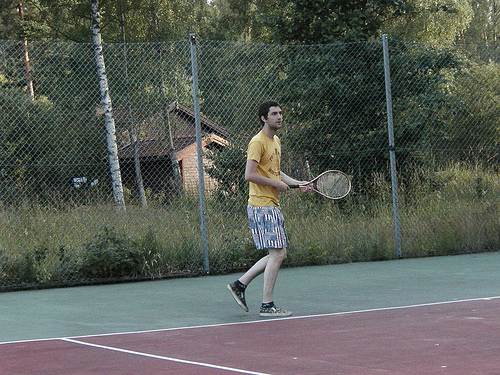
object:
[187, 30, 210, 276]
metal pole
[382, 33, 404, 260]
metal pole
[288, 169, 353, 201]
tennis racquet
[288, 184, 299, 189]
black grip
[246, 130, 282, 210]
t-shirt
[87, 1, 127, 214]
trunk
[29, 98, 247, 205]
building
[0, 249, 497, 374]
pavement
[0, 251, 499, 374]
tennis court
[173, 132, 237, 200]
wall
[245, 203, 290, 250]
shorts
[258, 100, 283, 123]
hair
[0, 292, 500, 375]
portion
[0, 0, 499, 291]
fence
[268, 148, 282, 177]
letters